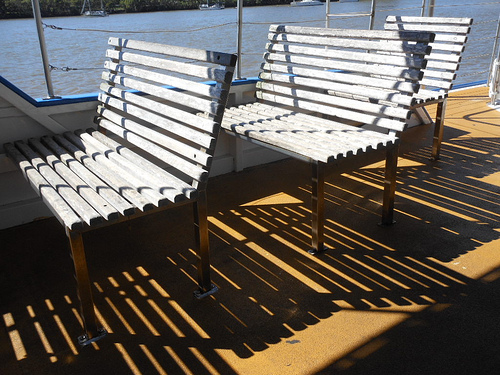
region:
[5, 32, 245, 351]
bench in front of other benches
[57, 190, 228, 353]
legs of bench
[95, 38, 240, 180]
slats of bench's back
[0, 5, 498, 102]
large body of water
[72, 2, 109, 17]
medium sized boat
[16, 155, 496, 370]
shadows of benches on deck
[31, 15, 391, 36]
safety wire on boat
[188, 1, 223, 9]
medium sized boat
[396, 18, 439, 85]
shadow cast onto middle bench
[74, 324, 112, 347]
bolts holding bench down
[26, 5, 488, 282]
Three benches on a boat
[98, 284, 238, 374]
Shadows of bench slats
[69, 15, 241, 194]
The back of a wooden bench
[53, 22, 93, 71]
A section of water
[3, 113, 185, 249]
The seat of a wooden bench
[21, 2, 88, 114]
A pole holding protective wires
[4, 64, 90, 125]
The blue edge of a boat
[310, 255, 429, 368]
The floor of a boat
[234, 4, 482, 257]
Two gray benches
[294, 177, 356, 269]
The leg of a bench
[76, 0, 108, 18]
the sailboat is on the side of the river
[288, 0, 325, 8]
a white boat on the water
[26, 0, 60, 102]
a metal bar on the side of the boat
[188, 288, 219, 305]
metal equipment bolting down the bench on the boat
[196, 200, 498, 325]
the sun casts shadows on the boat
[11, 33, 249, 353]
the bench is made out of wood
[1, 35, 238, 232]
the bench seat and back are white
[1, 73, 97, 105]
the railing on the boat is blue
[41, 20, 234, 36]
cable running between posts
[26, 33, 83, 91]
Wire railing connected to posts.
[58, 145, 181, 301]
Wood bench on boat.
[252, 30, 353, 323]
Wood bench on boat.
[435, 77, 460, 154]
Wood bench on boat.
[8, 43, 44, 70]
Water next to boat platform area.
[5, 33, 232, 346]
a weather worn wooden bench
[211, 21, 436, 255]
a weather worn wooden bench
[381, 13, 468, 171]
a weather worn wooden bench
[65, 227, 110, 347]
the metal bolted down leg of the bench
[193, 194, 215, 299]
the metal bolted down leg of the bench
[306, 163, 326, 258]
the metal bolted down leg of the bench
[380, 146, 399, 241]
the metal bolted down leg of the bench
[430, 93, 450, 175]
the metal bolted down leg of the bench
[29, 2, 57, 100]
a metal pole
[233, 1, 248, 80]
a metal pole